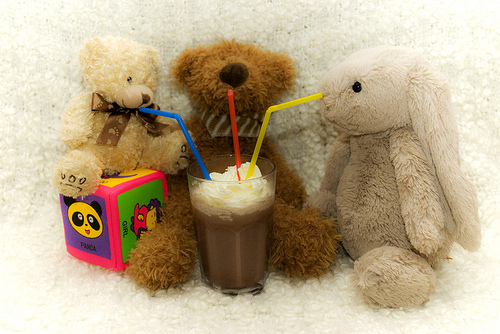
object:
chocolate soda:
[193, 198, 268, 288]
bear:
[126, 41, 340, 289]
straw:
[244, 94, 320, 178]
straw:
[139, 107, 213, 181]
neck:
[92, 90, 113, 103]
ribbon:
[90, 93, 169, 151]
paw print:
[109, 127, 119, 136]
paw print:
[116, 115, 123, 123]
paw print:
[93, 93, 103, 108]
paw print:
[108, 104, 114, 109]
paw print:
[148, 123, 154, 128]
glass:
[187, 154, 275, 296]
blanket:
[0, 0, 500, 333]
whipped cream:
[194, 162, 271, 202]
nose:
[321, 97, 334, 110]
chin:
[116, 99, 153, 108]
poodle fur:
[9, 9, 47, 169]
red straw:
[227, 90, 242, 183]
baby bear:
[54, 36, 192, 198]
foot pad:
[52, 164, 100, 196]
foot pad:
[170, 130, 194, 174]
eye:
[127, 77, 132, 81]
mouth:
[122, 100, 143, 108]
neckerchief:
[197, 107, 264, 137]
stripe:
[201, 110, 205, 120]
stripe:
[226, 116, 240, 133]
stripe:
[206, 113, 216, 127]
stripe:
[239, 118, 251, 134]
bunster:
[316, 52, 483, 309]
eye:
[352, 81, 362, 92]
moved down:
[325, 118, 349, 130]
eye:
[221, 58, 225, 61]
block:
[63, 165, 169, 272]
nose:
[220, 62, 248, 87]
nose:
[143, 94, 151, 104]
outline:
[60, 193, 102, 239]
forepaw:
[61, 127, 94, 148]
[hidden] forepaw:
[154, 111, 178, 134]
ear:
[409, 73, 481, 251]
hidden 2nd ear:
[413, 125, 452, 226]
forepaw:
[276, 173, 305, 207]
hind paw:
[126, 227, 199, 290]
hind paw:
[270, 211, 340, 275]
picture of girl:
[130, 197, 161, 239]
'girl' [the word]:
[122, 221, 128, 238]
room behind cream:
[190, 152, 274, 181]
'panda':
[63, 196, 103, 238]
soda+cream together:
[136, 89, 321, 289]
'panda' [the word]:
[81, 242, 97, 251]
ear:
[78, 37, 104, 66]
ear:
[144, 45, 158, 66]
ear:
[264, 51, 292, 95]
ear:
[171, 46, 205, 85]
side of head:
[240, 46, 293, 110]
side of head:
[175, 42, 230, 111]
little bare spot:
[304, 25, 308, 28]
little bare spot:
[131, 27, 136, 30]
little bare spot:
[253, 41, 256, 43]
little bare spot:
[51, 105, 55, 107]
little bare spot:
[47, 181, 50, 184]